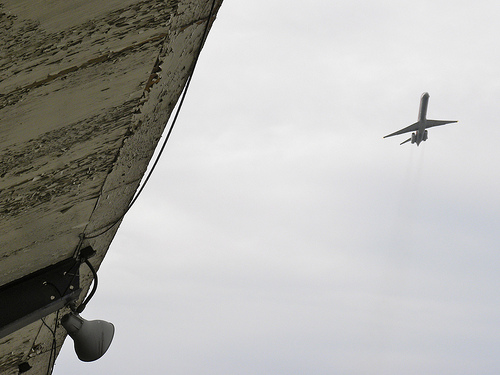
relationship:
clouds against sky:
[296, 210, 347, 253] [219, 298, 393, 372]